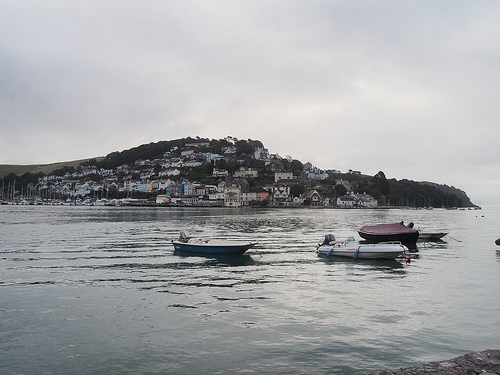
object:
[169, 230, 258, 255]
boat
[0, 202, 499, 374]
water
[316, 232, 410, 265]
boat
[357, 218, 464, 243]
boat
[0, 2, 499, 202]
sky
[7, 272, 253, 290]
ripple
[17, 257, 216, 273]
ripple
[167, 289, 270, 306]
ripple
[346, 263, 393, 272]
ripple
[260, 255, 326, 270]
ripple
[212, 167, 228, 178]
house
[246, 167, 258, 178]
house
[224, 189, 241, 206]
house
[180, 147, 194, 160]
house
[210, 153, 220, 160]
house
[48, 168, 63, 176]
tree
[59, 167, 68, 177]
tree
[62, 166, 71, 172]
tree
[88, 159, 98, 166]
tree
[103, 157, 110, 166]
tree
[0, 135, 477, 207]
hill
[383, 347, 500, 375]
shore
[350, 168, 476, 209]
end of hill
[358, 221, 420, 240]
cover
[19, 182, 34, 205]
sailboat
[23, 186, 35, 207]
sailboat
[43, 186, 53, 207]
sailboat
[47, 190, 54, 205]
sailboat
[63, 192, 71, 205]
sailboat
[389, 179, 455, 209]
forest